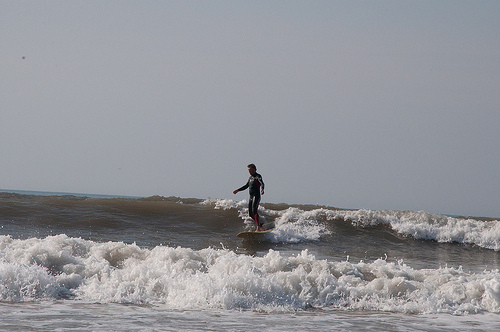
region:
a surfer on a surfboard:
[232, 156, 285, 246]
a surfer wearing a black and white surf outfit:
[234, 155, 271, 232]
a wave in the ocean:
[1, 235, 493, 325]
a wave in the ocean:
[13, 187, 498, 257]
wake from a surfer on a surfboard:
[276, 206, 323, 253]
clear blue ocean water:
[3, 185, 147, 198]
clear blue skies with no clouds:
[1, 4, 498, 213]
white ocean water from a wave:
[2, 230, 497, 322]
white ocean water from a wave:
[211, 189, 498, 259]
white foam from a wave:
[5, 301, 497, 328]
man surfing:
[222, 159, 272, 229]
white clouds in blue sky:
[28, 11, 85, 52]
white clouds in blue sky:
[387, 68, 425, 103]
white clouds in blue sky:
[317, 72, 398, 129]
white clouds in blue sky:
[394, 98, 439, 165]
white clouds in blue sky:
[260, 66, 307, 113]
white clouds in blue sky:
[171, 73, 219, 114]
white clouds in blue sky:
[101, 125, 146, 162]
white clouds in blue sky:
[141, 0, 203, 81]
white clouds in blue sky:
[50, 69, 134, 144]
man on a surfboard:
[235, 165, 270, 235]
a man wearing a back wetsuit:
[230, 160, 260, 230]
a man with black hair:
[230, 160, 260, 225]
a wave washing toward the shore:
[0, 230, 495, 310]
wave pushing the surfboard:
[205, 190, 495, 270]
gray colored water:
[0, 190, 495, 330]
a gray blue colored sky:
[0, 0, 495, 215]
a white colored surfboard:
[235, 225, 270, 235]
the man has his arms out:
[230, 160, 265, 220]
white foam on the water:
[7, 235, 494, 322]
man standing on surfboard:
[227, 156, 272, 223]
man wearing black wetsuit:
[231, 177, 274, 223]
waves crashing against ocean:
[0, 234, 357, 308]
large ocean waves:
[9, 194, 232, 289]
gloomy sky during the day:
[3, 4, 342, 139]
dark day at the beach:
[3, 2, 497, 329]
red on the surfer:
[253, 213, 261, 228]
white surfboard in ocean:
[235, 228, 310, 245]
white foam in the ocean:
[19, 233, 242, 315]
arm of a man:
[231, 186, 251, 193]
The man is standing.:
[217, 138, 290, 246]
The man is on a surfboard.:
[218, 147, 301, 248]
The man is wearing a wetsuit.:
[223, 133, 283, 249]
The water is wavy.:
[0, 176, 498, 329]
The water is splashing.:
[0, 175, 499, 330]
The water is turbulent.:
[1, 178, 499, 330]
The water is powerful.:
[2, 183, 499, 328]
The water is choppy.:
[1, 179, 498, 330]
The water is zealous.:
[0, 179, 498, 329]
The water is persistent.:
[1, 177, 498, 330]